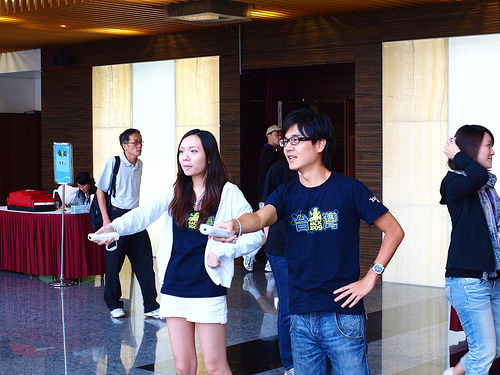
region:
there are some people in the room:
[111, 120, 498, 365]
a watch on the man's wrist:
[367, 260, 391, 276]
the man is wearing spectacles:
[276, 110, 342, 193]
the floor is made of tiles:
[14, 291, 44, 373]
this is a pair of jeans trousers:
[293, 317, 360, 371]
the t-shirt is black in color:
[295, 237, 344, 275]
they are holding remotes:
[69, 200, 279, 241]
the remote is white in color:
[198, 223, 223, 235]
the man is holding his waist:
[336, 265, 376, 320]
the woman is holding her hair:
[441, 125, 473, 173]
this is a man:
[237, 112, 397, 373]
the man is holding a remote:
[212, 110, 392, 372]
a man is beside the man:
[154, 131, 218, 373]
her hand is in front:
[78, 195, 162, 255]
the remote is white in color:
[84, 229, 122, 253]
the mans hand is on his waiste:
[321, 183, 402, 315]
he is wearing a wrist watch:
[370, 260, 385, 273]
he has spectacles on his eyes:
[278, 135, 301, 148]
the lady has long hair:
[208, 163, 222, 203]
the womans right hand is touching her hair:
[442, 140, 481, 197]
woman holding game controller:
[108, 131, 233, 315]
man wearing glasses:
[273, 96, 348, 223]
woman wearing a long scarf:
[428, 103, 498, 283]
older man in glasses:
[101, 123, 155, 243]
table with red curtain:
[13, 198, 103, 285]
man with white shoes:
[88, 291, 178, 328]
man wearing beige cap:
[251, 111, 305, 163]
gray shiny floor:
[8, 300, 120, 372]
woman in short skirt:
[138, 273, 240, 340]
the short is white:
[142, 283, 249, 338]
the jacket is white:
[106, 172, 301, 311]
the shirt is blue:
[255, 173, 408, 303]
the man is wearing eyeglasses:
[252, 115, 326, 172]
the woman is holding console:
[77, 132, 252, 268]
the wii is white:
[182, 215, 255, 254]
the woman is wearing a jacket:
[82, 136, 252, 286]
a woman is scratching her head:
[403, 93, 495, 206]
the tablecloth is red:
[2, 213, 109, 280]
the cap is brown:
[260, 124, 291, 140]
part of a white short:
[172, 304, 214, 331]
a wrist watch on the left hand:
[364, 260, 381, 277]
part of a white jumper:
[126, 215, 157, 230]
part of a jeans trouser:
[288, 317, 353, 354]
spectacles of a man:
[276, 133, 301, 153]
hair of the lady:
[208, 168, 220, 193]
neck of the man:
[298, 169, 314, 183]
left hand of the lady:
[203, 252, 220, 272]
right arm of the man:
[241, 213, 262, 225]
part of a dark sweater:
[443, 207, 487, 277]